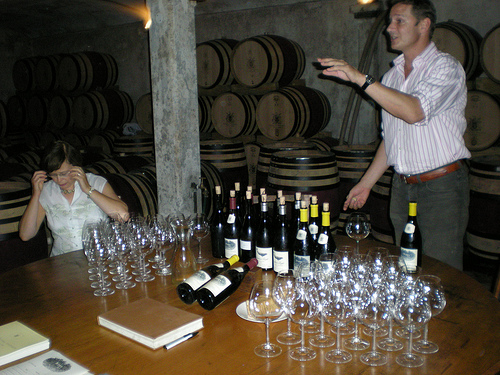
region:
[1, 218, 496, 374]
a very large brown table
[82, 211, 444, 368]
empty wine glasses set up in two groups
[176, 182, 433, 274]
multiple wine bottles standing upright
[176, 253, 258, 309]
two wine bottles laying on their sides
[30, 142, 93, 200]
woman with her hands to her glasses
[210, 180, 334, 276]
open bottles have corks in them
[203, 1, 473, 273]
man standing near wine bottles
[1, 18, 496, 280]
large barrels near a wall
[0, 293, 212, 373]
three books laying on their sides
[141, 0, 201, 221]
light partially hidden by a grey pillar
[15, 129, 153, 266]
lady wearing white top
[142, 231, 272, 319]
two wine bottles laying on table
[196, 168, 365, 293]
several wine bottles standing on table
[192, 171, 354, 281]
cork in the top of each wine bottle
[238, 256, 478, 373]
wine glasses on table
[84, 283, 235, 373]
pen and book on table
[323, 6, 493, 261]
guy wearing striped shirt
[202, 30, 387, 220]
barrels stacked on barrels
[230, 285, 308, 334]
white plate on table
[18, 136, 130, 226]
woman with brown hair wearing glasses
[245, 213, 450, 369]
wine glasses on the table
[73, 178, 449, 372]
wine glasses and bottles on the table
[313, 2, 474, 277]
a guy standing in front of the table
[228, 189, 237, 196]
a cork on a bottle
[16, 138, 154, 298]
a woman in front of the wine glasses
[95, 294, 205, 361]
a book and a pen on the table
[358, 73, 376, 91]
a watch on the guy's hand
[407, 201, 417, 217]
a yellow seal on the bottle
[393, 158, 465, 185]
a brown belt the guy is wearing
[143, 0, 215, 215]
a pillar in the room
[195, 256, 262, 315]
bottle of wine on table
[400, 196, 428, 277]
bottle of wine on table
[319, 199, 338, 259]
bottle of wine on table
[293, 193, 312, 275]
bottle of wine on table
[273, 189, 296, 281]
bottle of wine on table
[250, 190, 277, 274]
bottle of wine on table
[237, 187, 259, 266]
bottle of wine on table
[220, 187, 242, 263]
bottle of wine on table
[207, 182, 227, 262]
bottle of wine on table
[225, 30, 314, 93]
large wooden keg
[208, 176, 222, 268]
red wine bottle on table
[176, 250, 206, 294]
red wine bottle on table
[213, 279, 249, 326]
red wine bottle on table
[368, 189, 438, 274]
red wine bottle on table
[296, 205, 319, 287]
red wine bottle on table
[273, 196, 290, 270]
red wine bottle on table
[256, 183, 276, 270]
red wine bottle on table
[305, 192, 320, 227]
red wine bottle on table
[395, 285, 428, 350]
clear wine glass on table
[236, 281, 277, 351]
clear wine glass on table